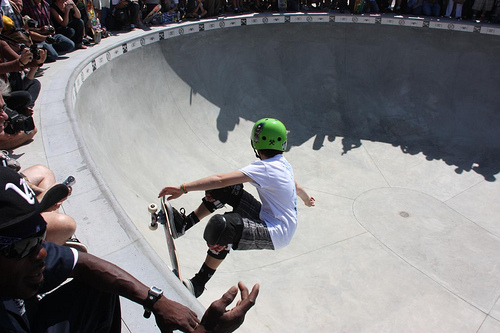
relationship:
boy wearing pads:
[158, 118, 315, 298] [192, 214, 234, 247]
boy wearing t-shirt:
[158, 118, 315, 298] [240, 155, 302, 250]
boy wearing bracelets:
[158, 118, 315, 298] [179, 182, 187, 193]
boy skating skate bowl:
[158, 116, 316, 300] [64, 16, 496, 332]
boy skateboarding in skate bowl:
[158, 116, 316, 300] [64, 16, 496, 332]